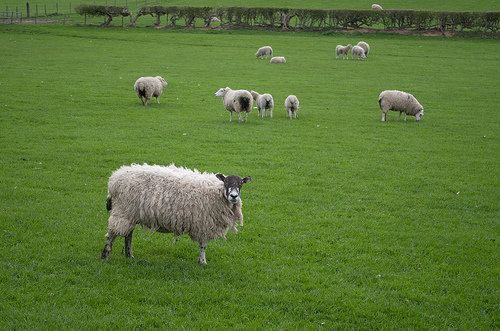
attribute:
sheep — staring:
[375, 87, 427, 125]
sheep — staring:
[282, 91, 300, 120]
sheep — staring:
[212, 80, 253, 122]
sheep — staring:
[132, 70, 167, 106]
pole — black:
[24, 0, 30, 17]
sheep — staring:
[97, 155, 253, 267]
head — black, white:
[214, 171, 257, 203]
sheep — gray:
[200, 85, 326, 117]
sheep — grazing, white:
[316, 30, 382, 66]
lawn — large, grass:
[4, 28, 498, 329]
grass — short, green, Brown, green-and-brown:
[1, 3, 499, 325]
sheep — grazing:
[374, 89, 432, 124]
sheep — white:
[104, 165, 251, 261]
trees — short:
[73, 1, 498, 46]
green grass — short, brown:
[0, 23, 498, 328]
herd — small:
[79, 21, 446, 271]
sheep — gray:
[285, 94, 300, 116]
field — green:
[1, 34, 498, 329]